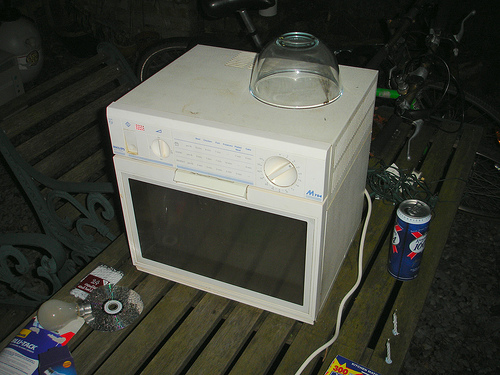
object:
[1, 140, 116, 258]
arm rest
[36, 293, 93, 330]
bulb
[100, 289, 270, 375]
chair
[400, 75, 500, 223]
wheel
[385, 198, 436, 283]
can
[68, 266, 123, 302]
book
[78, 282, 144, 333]
cd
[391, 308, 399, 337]
candle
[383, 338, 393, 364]
candle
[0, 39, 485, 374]
table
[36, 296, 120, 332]
light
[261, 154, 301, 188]
knob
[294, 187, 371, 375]
cord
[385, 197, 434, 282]
beverage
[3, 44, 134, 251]
bench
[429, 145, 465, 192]
bench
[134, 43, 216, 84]
wheel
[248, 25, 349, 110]
bowl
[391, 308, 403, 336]
candle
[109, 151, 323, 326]
oven door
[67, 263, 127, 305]
cigarette pack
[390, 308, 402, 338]
rope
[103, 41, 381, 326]
microwave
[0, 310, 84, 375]
book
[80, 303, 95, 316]
base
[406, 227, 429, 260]
design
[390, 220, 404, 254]
design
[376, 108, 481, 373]
slat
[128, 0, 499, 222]
bicycle